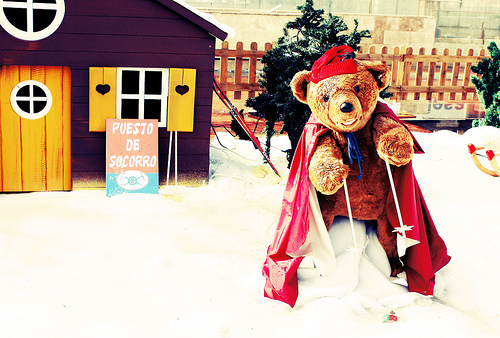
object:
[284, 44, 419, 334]
bear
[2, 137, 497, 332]
snow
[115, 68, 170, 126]
window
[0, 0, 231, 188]
house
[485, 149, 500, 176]
sled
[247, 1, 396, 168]
tree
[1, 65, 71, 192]
door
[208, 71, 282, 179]
skis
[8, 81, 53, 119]
round window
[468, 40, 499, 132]
tree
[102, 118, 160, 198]
sign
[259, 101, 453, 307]
cape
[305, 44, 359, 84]
red hat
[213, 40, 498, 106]
fence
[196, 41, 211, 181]
wall